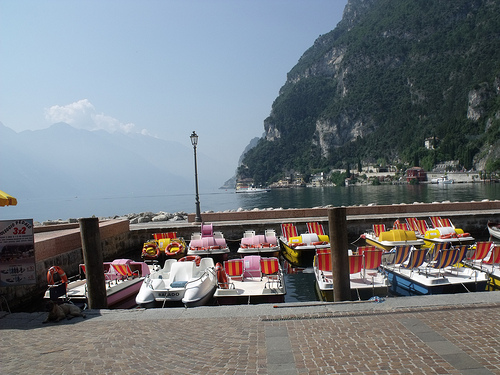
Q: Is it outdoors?
A: Yes, it is outdoors.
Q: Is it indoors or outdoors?
A: It is outdoors.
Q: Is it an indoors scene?
A: No, it is outdoors.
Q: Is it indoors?
A: No, it is outdoors.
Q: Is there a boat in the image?
A: Yes, there is a boat.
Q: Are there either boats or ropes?
A: Yes, there is a boat.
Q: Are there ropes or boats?
A: Yes, there is a boat.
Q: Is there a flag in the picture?
A: No, there are no flags.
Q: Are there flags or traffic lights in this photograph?
A: No, there are no flags or traffic lights.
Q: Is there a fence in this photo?
A: No, there are no fences.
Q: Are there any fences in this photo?
A: No, there are no fences.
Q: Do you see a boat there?
A: Yes, there is a boat.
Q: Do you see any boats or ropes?
A: Yes, there is a boat.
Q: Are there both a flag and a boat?
A: No, there is a boat but no flags.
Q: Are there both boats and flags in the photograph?
A: No, there is a boat but no flags.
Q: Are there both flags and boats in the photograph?
A: No, there is a boat but no flags.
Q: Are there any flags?
A: No, there are no flags.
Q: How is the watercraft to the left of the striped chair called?
A: The watercraft is a boat.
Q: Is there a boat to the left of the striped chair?
A: Yes, there is a boat to the left of the chair.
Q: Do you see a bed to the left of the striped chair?
A: No, there is a boat to the left of the chair.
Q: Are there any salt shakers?
A: No, there are no salt shakers.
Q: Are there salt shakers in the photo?
A: No, there are no salt shakers.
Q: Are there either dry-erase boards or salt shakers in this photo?
A: No, there are no salt shakers or dry-erase boards.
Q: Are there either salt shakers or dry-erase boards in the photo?
A: No, there are no salt shakers or dry-erase boards.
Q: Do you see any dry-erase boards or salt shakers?
A: No, there are no salt shakers or dry-erase boards.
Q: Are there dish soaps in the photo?
A: No, there are no dish soaps.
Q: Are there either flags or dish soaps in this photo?
A: No, there are no dish soaps or flags.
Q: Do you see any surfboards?
A: No, there are no surfboards.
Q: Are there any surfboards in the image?
A: No, there are no surfboards.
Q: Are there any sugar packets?
A: No, there are no sugar packets.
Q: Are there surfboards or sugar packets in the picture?
A: No, there are no sugar packets or surfboards.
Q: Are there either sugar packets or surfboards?
A: No, there are no sugar packets or surfboards.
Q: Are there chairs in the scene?
A: Yes, there is a chair.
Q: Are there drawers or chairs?
A: Yes, there is a chair.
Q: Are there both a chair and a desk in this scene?
A: No, there is a chair but no desks.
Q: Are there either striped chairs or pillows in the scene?
A: Yes, there is a striped chair.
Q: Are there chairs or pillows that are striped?
A: Yes, the chair is striped.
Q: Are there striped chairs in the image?
A: Yes, there is a striped chair.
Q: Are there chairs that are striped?
A: Yes, there is a chair that is striped.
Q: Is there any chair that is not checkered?
A: Yes, there is a striped chair.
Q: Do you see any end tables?
A: No, there are no end tables.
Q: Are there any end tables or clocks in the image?
A: No, there are no end tables or clocks.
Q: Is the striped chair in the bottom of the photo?
A: Yes, the chair is in the bottom of the image.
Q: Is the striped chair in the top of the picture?
A: No, the chair is in the bottom of the image.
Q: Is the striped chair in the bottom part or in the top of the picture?
A: The chair is in the bottom of the image.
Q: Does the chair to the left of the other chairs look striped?
A: Yes, the chair is striped.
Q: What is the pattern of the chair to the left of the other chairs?
A: The chair is striped.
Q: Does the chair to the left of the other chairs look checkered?
A: No, the chair is striped.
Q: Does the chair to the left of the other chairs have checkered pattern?
A: No, the chair is striped.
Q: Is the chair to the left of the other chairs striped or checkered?
A: The chair is striped.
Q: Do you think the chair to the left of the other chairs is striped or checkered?
A: The chair is striped.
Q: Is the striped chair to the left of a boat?
A: No, the chair is to the right of a boat.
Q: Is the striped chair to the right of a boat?
A: No, the chair is to the left of a boat.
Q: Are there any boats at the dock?
A: Yes, there are boats at the dock.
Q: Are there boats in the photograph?
A: Yes, there is a boat.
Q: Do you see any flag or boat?
A: Yes, there is a boat.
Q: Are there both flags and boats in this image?
A: No, there is a boat but no flags.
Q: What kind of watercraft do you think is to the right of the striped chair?
A: The watercraft is a boat.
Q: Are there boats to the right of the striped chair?
A: Yes, there is a boat to the right of the chair.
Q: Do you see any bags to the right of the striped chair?
A: No, there is a boat to the right of the chair.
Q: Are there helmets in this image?
A: No, there are no helmets.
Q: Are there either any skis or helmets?
A: No, there are no helmets or skis.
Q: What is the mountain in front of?
A: The mountain is in front of the ocean.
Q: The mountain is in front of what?
A: The mountain is in front of the ocean.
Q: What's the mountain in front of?
A: The mountain is in front of the ocean.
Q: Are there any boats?
A: Yes, there is a boat.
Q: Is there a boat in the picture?
A: Yes, there is a boat.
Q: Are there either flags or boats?
A: Yes, there is a boat.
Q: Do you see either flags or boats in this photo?
A: Yes, there is a boat.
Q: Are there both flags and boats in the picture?
A: No, there is a boat but no flags.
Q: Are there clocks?
A: No, there are no clocks.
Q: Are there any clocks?
A: No, there are no clocks.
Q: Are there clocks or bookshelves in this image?
A: No, there are no clocks or bookshelves.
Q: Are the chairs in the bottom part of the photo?
A: Yes, the chairs are in the bottom of the image.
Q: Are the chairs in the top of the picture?
A: No, the chairs are in the bottom of the image.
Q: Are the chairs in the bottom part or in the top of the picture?
A: The chairs are in the bottom of the image.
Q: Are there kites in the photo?
A: No, there are no kites.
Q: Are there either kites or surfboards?
A: No, there are no kites or surfboards.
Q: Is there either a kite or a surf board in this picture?
A: No, there are no kites or surfboards.